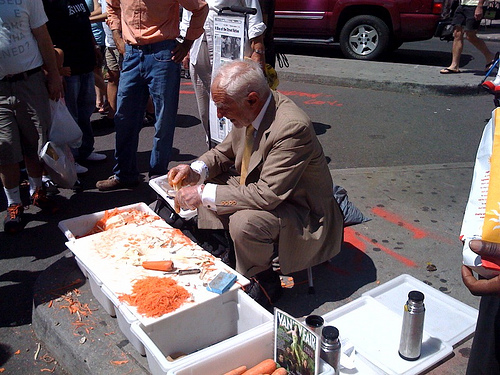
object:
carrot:
[141, 260, 175, 272]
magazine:
[271, 305, 321, 374]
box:
[171, 321, 337, 375]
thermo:
[396, 288, 426, 362]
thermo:
[319, 324, 343, 374]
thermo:
[304, 313, 325, 336]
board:
[312, 271, 480, 375]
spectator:
[92, 0, 211, 193]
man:
[163, 56, 347, 307]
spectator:
[42, 0, 110, 175]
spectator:
[0, 0, 66, 233]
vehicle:
[260, 0, 446, 63]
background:
[268, 0, 500, 171]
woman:
[435, 0, 498, 74]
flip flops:
[439, 67, 461, 74]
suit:
[190, 90, 347, 280]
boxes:
[126, 285, 284, 375]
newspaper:
[206, 14, 247, 150]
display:
[207, 14, 246, 145]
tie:
[239, 123, 257, 188]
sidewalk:
[272, 52, 500, 94]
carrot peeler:
[163, 268, 201, 275]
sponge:
[205, 270, 238, 295]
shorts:
[448, 3, 490, 32]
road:
[0, 71, 500, 375]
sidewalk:
[0, 160, 500, 374]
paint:
[370, 203, 429, 241]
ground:
[0, 36, 500, 372]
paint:
[178, 81, 344, 109]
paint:
[326, 223, 418, 278]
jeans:
[111, 38, 185, 184]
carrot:
[243, 357, 279, 375]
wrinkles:
[260, 178, 269, 185]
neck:
[242, 94, 271, 129]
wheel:
[337, 11, 393, 61]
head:
[208, 56, 272, 130]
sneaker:
[3, 200, 27, 237]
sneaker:
[30, 189, 64, 217]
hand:
[173, 183, 207, 214]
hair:
[215, 55, 272, 107]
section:
[137, 60, 165, 79]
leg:
[94, 45, 144, 191]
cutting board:
[64, 217, 253, 328]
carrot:
[116, 275, 192, 317]